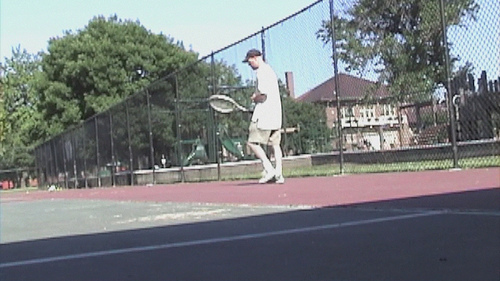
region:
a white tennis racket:
[208, 93, 254, 116]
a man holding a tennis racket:
[211, 50, 288, 182]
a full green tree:
[25, 13, 188, 155]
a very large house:
[283, 66, 415, 153]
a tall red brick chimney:
[282, 70, 297, 98]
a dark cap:
[241, 48, 263, 60]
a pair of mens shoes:
[258, 168, 284, 186]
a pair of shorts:
[247, 120, 282, 146]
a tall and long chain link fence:
[27, 0, 499, 187]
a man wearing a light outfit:
[238, 47, 286, 182]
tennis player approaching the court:
[209, 47, 282, 184]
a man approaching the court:
[210, 49, 284, 189]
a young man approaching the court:
[211, 50, 283, 179]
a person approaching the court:
[212, 48, 282, 186]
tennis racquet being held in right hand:
[209, 94, 254, 115]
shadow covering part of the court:
[3, 188, 498, 279]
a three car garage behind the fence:
[294, 71, 414, 153]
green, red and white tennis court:
[0, 164, 498, 279]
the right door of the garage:
[382, 125, 403, 150]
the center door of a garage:
[362, 129, 380, 148]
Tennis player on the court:
[206, 36, 311, 197]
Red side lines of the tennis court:
[39, 174, 372, 211]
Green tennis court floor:
[2, 196, 316, 239]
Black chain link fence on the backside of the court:
[50, 68, 237, 182]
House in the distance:
[281, 68, 430, 150]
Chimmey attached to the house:
[282, 66, 297, 106]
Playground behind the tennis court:
[168, 126, 254, 165]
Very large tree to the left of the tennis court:
[28, 13, 242, 157]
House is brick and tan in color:
[326, 104, 415, 149]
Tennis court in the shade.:
[6, 180, 498, 275]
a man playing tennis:
[138, 29, 364, 248]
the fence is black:
[136, 19, 378, 215]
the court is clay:
[171, 9, 403, 274]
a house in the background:
[202, 33, 431, 234]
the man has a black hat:
[206, 29, 396, 206]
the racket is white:
[186, 35, 358, 189]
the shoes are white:
[207, 31, 328, 191]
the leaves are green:
[54, 31, 344, 231]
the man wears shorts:
[179, 20, 344, 232]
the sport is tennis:
[191, 26, 313, 200]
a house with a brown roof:
[285, 70, 410, 150]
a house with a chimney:
[282, 65, 412, 145]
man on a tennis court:
[207, 45, 282, 180]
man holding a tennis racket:
[205, 47, 300, 179]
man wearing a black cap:
[207, 47, 282, 179]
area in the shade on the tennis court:
[0, 190, 497, 275]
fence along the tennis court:
[30, 0, 495, 185]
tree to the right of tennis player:
[312, 0, 467, 140]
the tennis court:
[0, 166, 495, 271]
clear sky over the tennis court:
[0, 1, 496, 91]